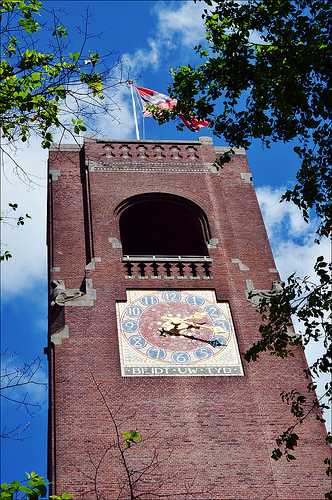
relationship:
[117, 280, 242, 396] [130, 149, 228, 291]
clock on building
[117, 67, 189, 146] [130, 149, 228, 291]
flag on building